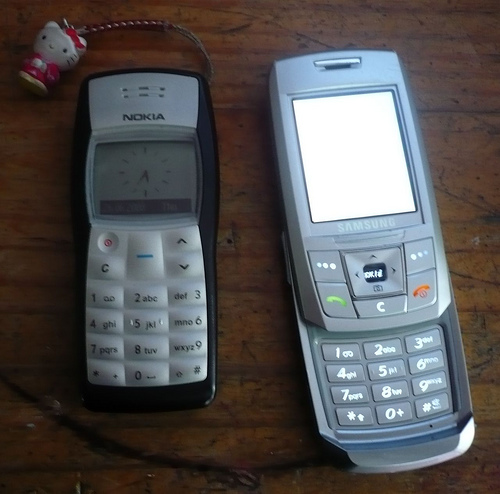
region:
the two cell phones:
[73, 48, 474, 473]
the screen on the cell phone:
[92, 141, 198, 213]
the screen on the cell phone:
[292, 90, 416, 222]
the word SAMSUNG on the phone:
[337, 215, 394, 232]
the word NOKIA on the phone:
[122, 113, 164, 121]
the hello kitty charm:
[17, 20, 87, 92]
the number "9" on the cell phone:
[418, 379, 427, 391]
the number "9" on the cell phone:
[194, 338, 202, 350]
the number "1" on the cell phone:
[90, 291, 95, 301]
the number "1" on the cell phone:
[333, 345, 340, 357]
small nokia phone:
[65, 67, 234, 428]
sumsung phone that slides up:
[260, 49, 481, 477]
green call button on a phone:
[313, 279, 360, 331]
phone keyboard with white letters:
[312, 336, 460, 436]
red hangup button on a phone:
[405, 275, 445, 311]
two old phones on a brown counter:
[73, 45, 481, 464]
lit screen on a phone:
[269, 40, 452, 316]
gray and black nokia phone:
[69, 61, 231, 431]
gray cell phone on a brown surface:
[260, 41, 479, 478]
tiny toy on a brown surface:
[10, 15, 91, 96]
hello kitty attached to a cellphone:
[23, 18, 86, 100]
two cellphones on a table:
[26, 30, 488, 477]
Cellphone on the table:
[250, 36, 485, 474]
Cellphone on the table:
[71, 68, 221, 415]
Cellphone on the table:
[261, 43, 474, 478]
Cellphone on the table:
[253, 33, 478, 477]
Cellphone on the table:
[66, 59, 240, 414]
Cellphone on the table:
[258, 33, 449, 470]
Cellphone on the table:
[84, 56, 234, 422]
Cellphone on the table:
[69, 67, 216, 416]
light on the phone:
[254, 31, 479, 231]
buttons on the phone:
[310, 313, 463, 435]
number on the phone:
[313, 333, 369, 373]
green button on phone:
[312, 277, 358, 317]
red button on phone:
[396, 272, 439, 311]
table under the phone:
[228, 342, 292, 435]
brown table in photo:
[214, 287, 281, 420]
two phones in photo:
[11, 61, 481, 418]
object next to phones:
[2, 13, 122, 108]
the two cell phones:
[69, 45, 474, 474]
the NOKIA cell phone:
[71, 68, 218, 411]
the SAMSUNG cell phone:
[267, 49, 475, 473]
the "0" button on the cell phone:
[375, 400, 412, 424]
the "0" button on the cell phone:
[125, 360, 170, 385]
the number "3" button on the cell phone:
[167, 281, 207, 306]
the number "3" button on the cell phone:
[403, 327, 440, 352]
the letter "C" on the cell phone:
[100, 262, 110, 272]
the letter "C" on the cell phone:
[375, 300, 385, 312]